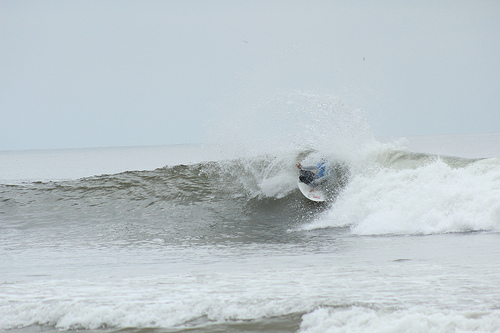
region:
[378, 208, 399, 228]
white waves crashing in water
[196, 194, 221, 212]
white waves crashing in water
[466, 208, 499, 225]
white waves crashing in water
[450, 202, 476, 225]
white waves crashing in water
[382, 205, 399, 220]
white waves crashing in water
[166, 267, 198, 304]
white waves crashing in water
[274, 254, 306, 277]
white waves crashing in water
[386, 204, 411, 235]
white waves crashing in water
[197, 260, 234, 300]
white waves crashing in water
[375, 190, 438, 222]
white waves crashing in water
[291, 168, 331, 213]
the surfboard is white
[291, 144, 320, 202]
the surfboard is white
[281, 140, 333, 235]
the surfboard is white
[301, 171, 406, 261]
white splashes of water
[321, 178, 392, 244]
white splashes of water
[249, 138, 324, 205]
white splashes of water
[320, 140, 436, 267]
white splashes of water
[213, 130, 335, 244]
white splashes of water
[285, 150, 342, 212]
surfer riding a wave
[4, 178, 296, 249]
swell of the wave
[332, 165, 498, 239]
white foam of the wave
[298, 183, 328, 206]
white surfboard on the wave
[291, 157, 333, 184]
surfer obscured by the wave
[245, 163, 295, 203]
path of surfboard on the wave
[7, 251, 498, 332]
foamy water in front of wave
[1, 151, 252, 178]
calm waters behind the wave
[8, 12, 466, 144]
hazy sky above the water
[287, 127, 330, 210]
surfer on a surfboard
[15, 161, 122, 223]
This is a portion of the sea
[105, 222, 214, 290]
This is a portion of the sea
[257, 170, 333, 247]
This is a portion of the sea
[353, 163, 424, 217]
This is a portion of the sea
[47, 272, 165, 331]
This is a portion of the sea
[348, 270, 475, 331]
This is a portion of the sea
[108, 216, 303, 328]
This is a portion of the sea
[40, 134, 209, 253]
This is a portion of the sea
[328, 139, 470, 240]
This is a portion of the sea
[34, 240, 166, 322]
This is a portion of the sea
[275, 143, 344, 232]
a person is surfing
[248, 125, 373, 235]
a person is surfing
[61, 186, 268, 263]
the water is gray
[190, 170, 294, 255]
the water is gray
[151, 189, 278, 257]
the water is gray